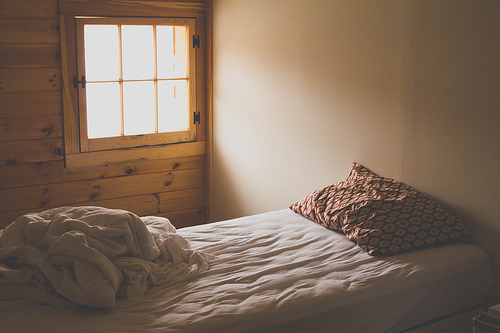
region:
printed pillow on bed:
[297, 158, 477, 247]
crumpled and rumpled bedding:
[2, 208, 207, 300]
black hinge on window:
[192, 29, 205, 53]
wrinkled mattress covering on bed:
[213, 215, 335, 302]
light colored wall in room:
[270, 33, 397, 123]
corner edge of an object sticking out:
[469, 300, 499, 331]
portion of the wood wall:
[120, 163, 200, 201]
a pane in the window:
[120, 82, 159, 135]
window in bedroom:
[47, 7, 224, 169]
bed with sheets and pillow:
[7, 172, 478, 327]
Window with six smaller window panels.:
[76, 18, 199, 145]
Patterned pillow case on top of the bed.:
[303, 153, 478, 252]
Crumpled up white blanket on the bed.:
[5, 193, 212, 311]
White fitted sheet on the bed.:
[11, 223, 498, 330]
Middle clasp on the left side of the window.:
[70, 73, 90, 92]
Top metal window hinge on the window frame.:
[188, 30, 205, 52]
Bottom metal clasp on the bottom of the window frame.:
[193, 109, 206, 129]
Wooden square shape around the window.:
[57, 4, 207, 164]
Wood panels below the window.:
[3, 156, 205, 226]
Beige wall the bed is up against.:
[216, 1, 498, 243]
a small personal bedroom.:
[31, 23, 451, 315]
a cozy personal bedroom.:
[38, 13, 465, 310]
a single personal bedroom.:
[2, 6, 461, 300]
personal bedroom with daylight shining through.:
[33, 18, 466, 301]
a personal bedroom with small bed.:
[25, 6, 460, 296]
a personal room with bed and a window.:
[45, 11, 431, 305]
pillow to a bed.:
[301, 153, 473, 259]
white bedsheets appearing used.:
[21, 197, 242, 292]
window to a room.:
[61, 18, 226, 161]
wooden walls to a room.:
[12, 26, 61, 184]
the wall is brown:
[12, 100, 67, 186]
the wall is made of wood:
[17, 115, 64, 195]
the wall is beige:
[236, 63, 303, 139]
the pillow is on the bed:
[221, 165, 458, 327]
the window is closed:
[53, 12, 225, 177]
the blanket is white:
[19, 215, 304, 297]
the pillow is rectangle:
[296, 167, 421, 281]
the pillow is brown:
[294, 160, 451, 273]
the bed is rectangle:
[10, 212, 435, 329]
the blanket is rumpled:
[33, 205, 236, 320]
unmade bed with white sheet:
[41, 105, 490, 330]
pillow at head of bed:
[285, 157, 475, 255]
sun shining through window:
[76, 18, 200, 145]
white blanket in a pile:
[19, 190, 199, 297]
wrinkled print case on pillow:
[337, 186, 399, 221]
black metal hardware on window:
[190, 108, 202, 130]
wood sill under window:
[54, 136, 209, 174]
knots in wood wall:
[43, 142, 65, 166]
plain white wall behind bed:
[291, 70, 443, 169]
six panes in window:
[80, 20, 195, 144]